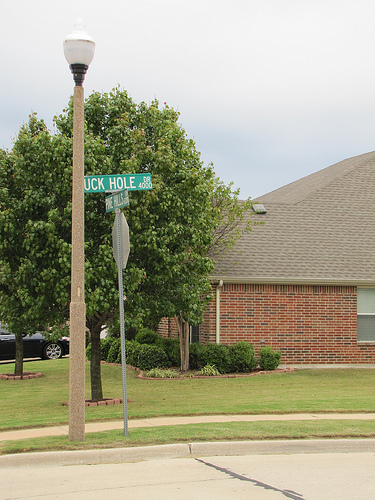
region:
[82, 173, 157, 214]
Two street signs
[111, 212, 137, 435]
The back of a stop sign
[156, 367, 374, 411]
A nicely mowed green grassy lawn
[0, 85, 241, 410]
A tall green tree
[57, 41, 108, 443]
A very tall lamp post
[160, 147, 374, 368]
A brick house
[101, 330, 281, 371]
A cluster of green bushes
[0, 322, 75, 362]
A black car parked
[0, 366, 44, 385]
Red bricks around the bottom of the tree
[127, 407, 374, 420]
A gray cement sidewalk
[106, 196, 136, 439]
this is a sign post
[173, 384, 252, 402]
the grass is green in color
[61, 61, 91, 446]
this is a poll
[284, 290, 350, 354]
this is a wall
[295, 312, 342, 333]
the wall is made of bricks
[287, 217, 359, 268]
this is a roof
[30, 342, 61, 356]
this is a car packed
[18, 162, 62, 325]
this is a tree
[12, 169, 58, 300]
the leaves are green in color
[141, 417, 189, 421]
this is a foot path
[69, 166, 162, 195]
Green sign with white writing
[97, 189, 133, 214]
Green sign with white writing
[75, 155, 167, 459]
Three signs on a metal sign post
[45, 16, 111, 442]
Large street light on brown post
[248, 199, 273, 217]
Small skylight on roof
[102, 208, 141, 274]
Silver metal stop sign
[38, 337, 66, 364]
Rubber and metal car tire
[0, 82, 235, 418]
Large tree with green foliage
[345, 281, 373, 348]
Glass window with white trim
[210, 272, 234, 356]
White metal gutter downspout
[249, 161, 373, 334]
this is a house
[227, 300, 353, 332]
the walls are made of bricks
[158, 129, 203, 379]
a tree is beside the house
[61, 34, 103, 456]
this is a light post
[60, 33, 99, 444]
the light post is tall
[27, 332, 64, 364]
this is a car parked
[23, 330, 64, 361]
the car is black in color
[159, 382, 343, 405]
the grass is well treamed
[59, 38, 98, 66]
the bulb is white in color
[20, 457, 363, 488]
the road is clear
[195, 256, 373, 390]
Wall of red brick house.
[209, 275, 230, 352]
Down drain of rain gutter.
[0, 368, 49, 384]
Red brick landscaping around tree.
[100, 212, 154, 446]
Back of stop sign next to street.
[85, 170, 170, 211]
Street names on signs above stop sign.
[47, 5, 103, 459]
Lamp post on side of road.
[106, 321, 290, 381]
Shrubbery landscaping around house.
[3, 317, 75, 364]
Black car parked in driveway.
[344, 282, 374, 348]
Window on side of house.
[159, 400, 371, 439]
Sidewalk running next to house.